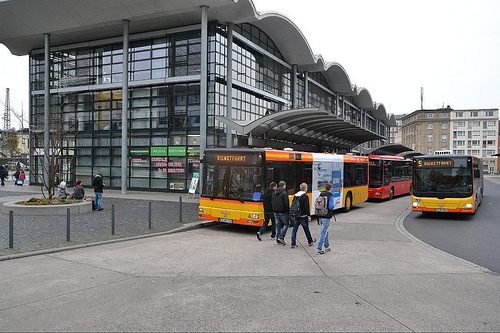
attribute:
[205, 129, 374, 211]
bus — parked, red, orange, in motion, yellow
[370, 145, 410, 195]
bus — red, parked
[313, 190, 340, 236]
person — standing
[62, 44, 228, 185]
building — glass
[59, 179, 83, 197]
people — sitting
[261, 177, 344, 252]
people — walking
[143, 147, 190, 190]
advertisement — written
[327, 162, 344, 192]
paper — blue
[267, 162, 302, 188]
window — tinted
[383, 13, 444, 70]
sky — cloudy